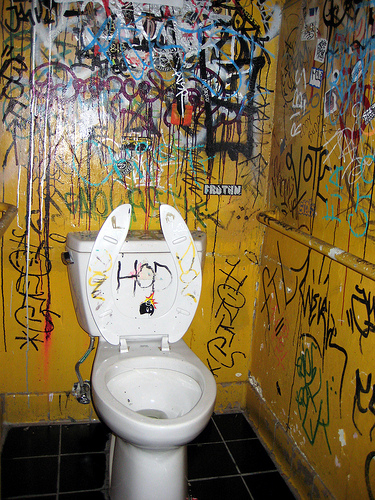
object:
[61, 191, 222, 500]
toilet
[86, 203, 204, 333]
graffiti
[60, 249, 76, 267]
handle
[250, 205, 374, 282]
rail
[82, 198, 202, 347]
seat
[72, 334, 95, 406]
pipe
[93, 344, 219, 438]
bowl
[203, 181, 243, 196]
sticker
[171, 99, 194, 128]
red fuse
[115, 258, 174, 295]
hod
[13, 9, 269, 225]
paint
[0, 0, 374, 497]
bathroom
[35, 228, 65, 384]
paint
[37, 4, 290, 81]
paint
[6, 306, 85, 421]
wall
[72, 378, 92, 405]
control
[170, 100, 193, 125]
sticker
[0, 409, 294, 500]
floor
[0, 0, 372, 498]
graffiti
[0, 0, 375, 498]
wall